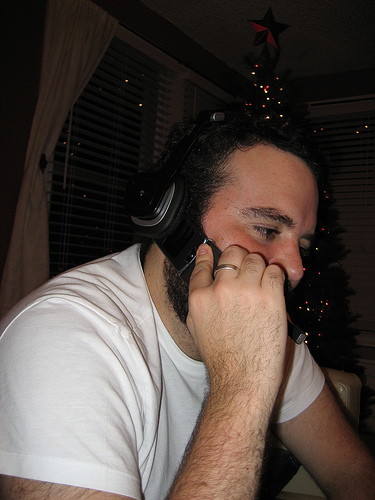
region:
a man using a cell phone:
[148, 194, 257, 301]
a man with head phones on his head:
[130, 112, 250, 248]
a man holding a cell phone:
[172, 200, 228, 312]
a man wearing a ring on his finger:
[205, 237, 239, 284]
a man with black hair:
[144, 123, 331, 254]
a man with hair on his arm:
[187, 371, 249, 488]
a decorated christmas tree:
[196, 22, 303, 166]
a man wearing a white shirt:
[63, 204, 239, 485]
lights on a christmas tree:
[244, 65, 304, 125]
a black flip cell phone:
[169, 200, 236, 300]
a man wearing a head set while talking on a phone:
[0, 109, 371, 496]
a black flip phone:
[145, 199, 250, 293]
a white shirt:
[4, 264, 154, 464]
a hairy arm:
[171, 345, 267, 496]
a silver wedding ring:
[206, 255, 237, 275]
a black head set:
[126, 109, 278, 327]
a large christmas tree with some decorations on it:
[202, 43, 341, 374]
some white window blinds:
[49, 88, 170, 253]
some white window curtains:
[11, 34, 99, 277]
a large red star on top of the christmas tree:
[242, 6, 301, 53]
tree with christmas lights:
[237, 31, 293, 135]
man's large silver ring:
[206, 260, 249, 272]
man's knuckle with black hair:
[265, 258, 284, 296]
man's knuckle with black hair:
[237, 251, 257, 288]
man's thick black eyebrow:
[229, 200, 297, 226]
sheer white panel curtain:
[8, 6, 122, 266]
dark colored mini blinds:
[47, 28, 175, 253]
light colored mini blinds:
[296, 125, 372, 332]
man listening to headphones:
[9, 88, 373, 498]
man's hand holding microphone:
[174, 210, 309, 399]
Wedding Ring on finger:
[212, 261, 238, 274]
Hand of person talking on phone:
[184, 240, 290, 376]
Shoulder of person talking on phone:
[24, 296, 125, 395]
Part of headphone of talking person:
[116, 165, 186, 227]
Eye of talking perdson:
[247, 222, 285, 240]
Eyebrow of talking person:
[239, 204, 300, 223]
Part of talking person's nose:
[284, 235, 308, 285]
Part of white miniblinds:
[87, 102, 129, 149]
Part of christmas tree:
[242, 63, 286, 117]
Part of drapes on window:
[48, 32, 75, 81]